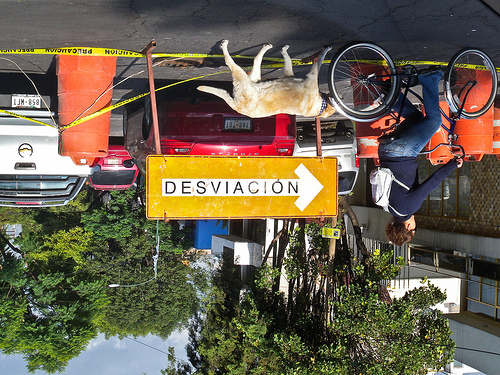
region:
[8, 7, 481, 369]
the picture is upside down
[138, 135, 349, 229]
a yellow sign with a white arrow on it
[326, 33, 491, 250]
a person on a bicycle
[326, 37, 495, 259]
the person is riding a bicycle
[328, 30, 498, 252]
the person on the bicycle is wearing a white backpack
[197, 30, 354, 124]
a dog is walking on the road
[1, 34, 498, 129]
yellow caution tape separates the cars from the pedestrians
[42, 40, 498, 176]
large orange traffic cones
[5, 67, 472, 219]
cars are behind the cones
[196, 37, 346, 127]
the dog is beige in color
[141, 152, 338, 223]
a yellow street sign in the middle of the road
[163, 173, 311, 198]
black lettering on a white arrow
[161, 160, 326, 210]
a white arrow on a yellow sign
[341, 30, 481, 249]
a woman riding a bicycle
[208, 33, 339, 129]
a white and yellow dog walking on the street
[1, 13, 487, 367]
an upside down street scene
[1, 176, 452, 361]
trees growing next to the road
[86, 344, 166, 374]
clear blue skies over the scene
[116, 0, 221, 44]
black asphalt surface of the road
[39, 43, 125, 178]
an orange blockade barrel in the road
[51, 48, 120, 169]
a bright orange traffic cone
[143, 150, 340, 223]
a bright yellow sign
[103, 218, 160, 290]
a tall metal light post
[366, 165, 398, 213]
a white backpack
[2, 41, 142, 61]
some yellow caution tape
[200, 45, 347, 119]
a full grown golden lab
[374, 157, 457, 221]
a dark blue sweater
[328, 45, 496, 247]
a woman riding a bike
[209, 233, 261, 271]
a small concrete balcony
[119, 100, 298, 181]
a small red sedan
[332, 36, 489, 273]
a man is riding a bicycle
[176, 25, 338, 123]
a dog is behind the bike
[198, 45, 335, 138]
the dog is brown in colour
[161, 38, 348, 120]
the dog has a black collar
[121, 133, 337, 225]
a yellow signboard wth a white arrow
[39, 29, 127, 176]
an orange dust bin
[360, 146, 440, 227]
the man has a backpack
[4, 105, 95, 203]
a white car is packed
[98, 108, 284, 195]
two red parked cars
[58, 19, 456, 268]
This picture is upside down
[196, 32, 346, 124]
A dog that is a yellow labarador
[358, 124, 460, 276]
A dark haired person wearing a blue shirt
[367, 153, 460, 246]
Person with dark hair wearing a white backpack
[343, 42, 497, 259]
A person riding a bike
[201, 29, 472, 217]
The dog is following the bike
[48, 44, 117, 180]
A large orange barrel used to block traffic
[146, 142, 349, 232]
The sign is not upside down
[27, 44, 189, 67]
Yellow caution tape on the ground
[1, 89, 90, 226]
A white car that is parked